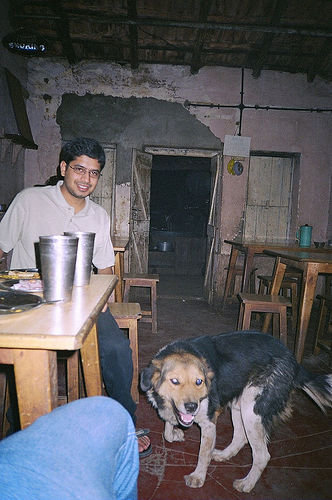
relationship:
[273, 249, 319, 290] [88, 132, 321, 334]
table in restaurant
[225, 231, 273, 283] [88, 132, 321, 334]
table in restaurant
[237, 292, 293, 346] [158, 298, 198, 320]
stool on floor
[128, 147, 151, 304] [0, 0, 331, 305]
door to building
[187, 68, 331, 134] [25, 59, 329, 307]
black piping along wall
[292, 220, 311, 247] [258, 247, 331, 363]
pitcher on table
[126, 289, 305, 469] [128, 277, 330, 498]
dog standing on floor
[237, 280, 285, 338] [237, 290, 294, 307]
stool with seat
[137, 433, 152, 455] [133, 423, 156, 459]
toes of foot in sandal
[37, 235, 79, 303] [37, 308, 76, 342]
cup on table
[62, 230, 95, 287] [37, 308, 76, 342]
cup on table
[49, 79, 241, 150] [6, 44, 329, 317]
paint on wall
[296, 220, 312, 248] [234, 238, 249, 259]
container on table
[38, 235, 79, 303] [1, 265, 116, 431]
cup on table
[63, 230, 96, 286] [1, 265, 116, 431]
cup on table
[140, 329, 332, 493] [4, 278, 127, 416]
dog standing near table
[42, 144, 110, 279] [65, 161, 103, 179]
man with glasses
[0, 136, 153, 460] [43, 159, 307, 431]
man in restaurant